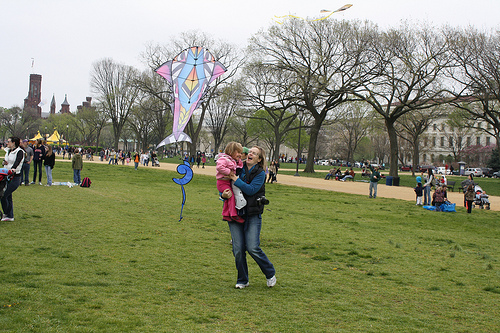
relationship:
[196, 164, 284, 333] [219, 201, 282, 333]
she wearing jeans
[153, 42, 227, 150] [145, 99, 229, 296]
flying kite flying